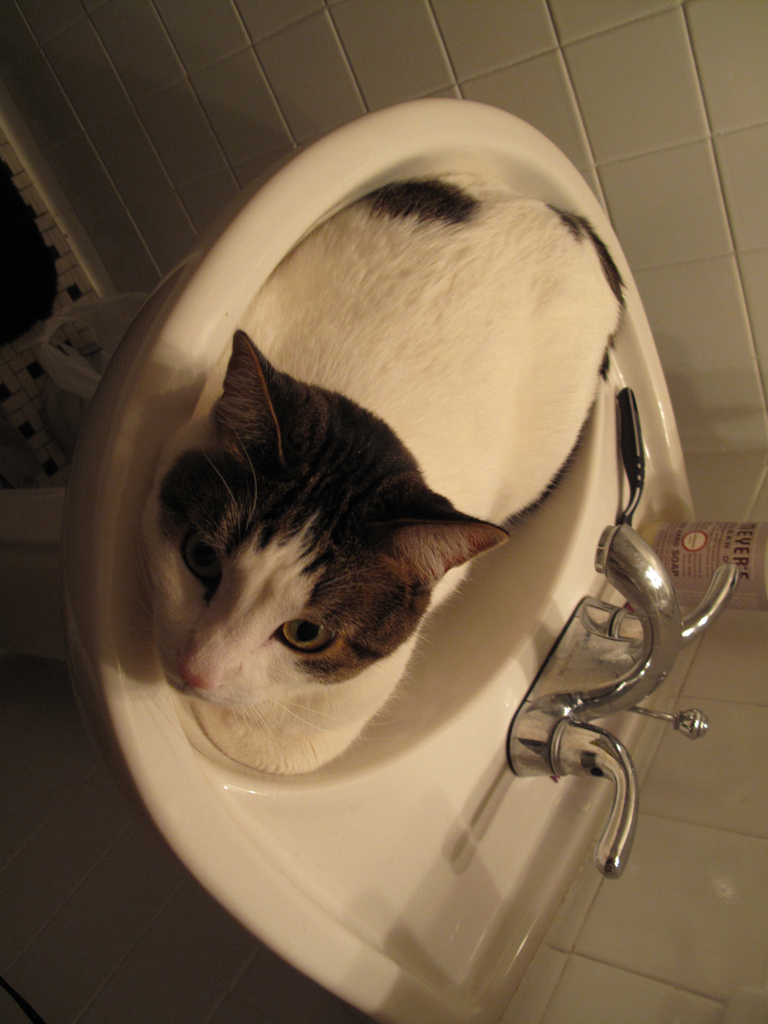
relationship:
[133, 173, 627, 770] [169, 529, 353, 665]
cat has eyes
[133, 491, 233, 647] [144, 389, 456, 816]
whisker on cat's face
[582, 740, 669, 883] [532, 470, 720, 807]
handle to faucet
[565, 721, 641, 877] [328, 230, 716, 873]
handle on top of sink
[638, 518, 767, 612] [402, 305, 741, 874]
bottle on top of basin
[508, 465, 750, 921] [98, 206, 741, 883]
faucet attached to sink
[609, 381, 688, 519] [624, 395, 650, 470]
handle with line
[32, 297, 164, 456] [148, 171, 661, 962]
plastic under lavatory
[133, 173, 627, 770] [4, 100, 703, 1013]
cat lying in sink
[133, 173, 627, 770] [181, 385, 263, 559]
cat has whiskers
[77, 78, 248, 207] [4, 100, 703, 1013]
tiles next to sink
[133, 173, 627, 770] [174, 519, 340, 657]
cat has two eyes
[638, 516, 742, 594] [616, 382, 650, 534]
bottle next to razor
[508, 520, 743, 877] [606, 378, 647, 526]
faucet next to razor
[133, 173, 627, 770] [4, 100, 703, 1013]
cat inside a sink